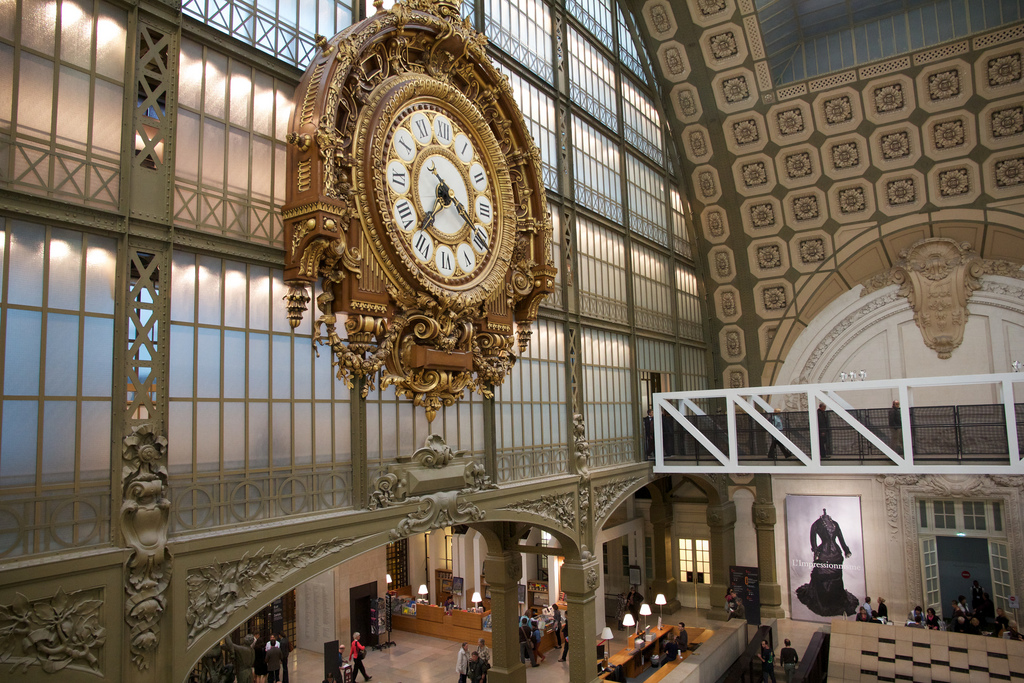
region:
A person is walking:
[351, 632, 375, 678]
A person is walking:
[450, 635, 473, 680]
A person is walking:
[778, 633, 799, 679]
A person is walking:
[759, 633, 776, 679]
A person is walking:
[621, 581, 645, 620]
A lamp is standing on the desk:
[415, 579, 434, 603]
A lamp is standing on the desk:
[468, 585, 487, 609]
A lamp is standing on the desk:
[596, 619, 619, 673]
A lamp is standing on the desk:
[618, 600, 638, 652]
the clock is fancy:
[276, 0, 553, 413]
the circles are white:
[374, 110, 496, 275]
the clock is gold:
[272, 8, 558, 421]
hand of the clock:
[424, 172, 494, 252]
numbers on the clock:
[387, 106, 492, 274]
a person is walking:
[345, 633, 372, 676]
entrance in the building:
[939, 542, 991, 626]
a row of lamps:
[596, 594, 664, 640]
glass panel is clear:
[171, 245, 200, 319]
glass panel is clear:
[196, 259, 222, 324]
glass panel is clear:
[222, 254, 242, 330]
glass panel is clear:
[167, 319, 196, 397]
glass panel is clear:
[193, 325, 217, 399]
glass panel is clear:
[218, 325, 244, 399]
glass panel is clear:
[243, 330, 273, 400]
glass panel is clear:
[266, 330, 293, 400]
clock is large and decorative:
[290, 2, 560, 415]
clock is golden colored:
[272, 0, 561, 440]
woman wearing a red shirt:
[345, 631, 372, 679]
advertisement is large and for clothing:
[783, 489, 870, 619]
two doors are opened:
[915, 530, 1020, 632]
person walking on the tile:
[262, 629, 289, 680]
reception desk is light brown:
[384, 585, 568, 655]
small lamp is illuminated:
[620, 610, 634, 650]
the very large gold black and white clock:
[280, 14, 557, 398]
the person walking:
[345, 627, 366, 678]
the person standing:
[449, 636, 469, 679]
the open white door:
[994, 535, 1015, 628]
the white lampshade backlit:
[598, 622, 614, 641]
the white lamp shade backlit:
[623, 610, 634, 626]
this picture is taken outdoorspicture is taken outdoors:
[167, 407, 203, 414]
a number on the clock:
[452, 236, 479, 263]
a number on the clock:
[434, 242, 467, 287]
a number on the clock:
[419, 248, 438, 261]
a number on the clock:
[440, 106, 470, 133]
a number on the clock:
[358, 112, 394, 201]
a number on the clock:
[389, 180, 427, 264]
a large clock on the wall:
[273, 48, 613, 361]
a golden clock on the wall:
[261, 18, 642, 373]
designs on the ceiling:
[609, 66, 1021, 496]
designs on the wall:
[75, 375, 644, 590]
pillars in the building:
[455, 473, 740, 677]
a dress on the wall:
[744, 467, 947, 673]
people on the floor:
[828, 566, 1015, 674]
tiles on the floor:
[837, 614, 940, 672]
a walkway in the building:
[621, 326, 1017, 469]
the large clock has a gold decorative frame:
[279, 0, 556, 427]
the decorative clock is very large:
[282, 0, 555, 421]